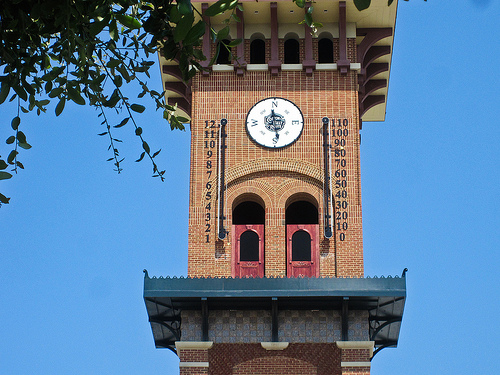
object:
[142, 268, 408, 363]
umbrella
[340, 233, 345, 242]
number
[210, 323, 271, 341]
white wall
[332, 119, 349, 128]
number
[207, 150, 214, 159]
number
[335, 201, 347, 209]
number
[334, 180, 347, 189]
number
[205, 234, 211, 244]
number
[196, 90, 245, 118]
brick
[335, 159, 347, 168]
number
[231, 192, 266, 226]
window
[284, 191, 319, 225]
window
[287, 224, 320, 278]
door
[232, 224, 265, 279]
door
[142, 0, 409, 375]
building